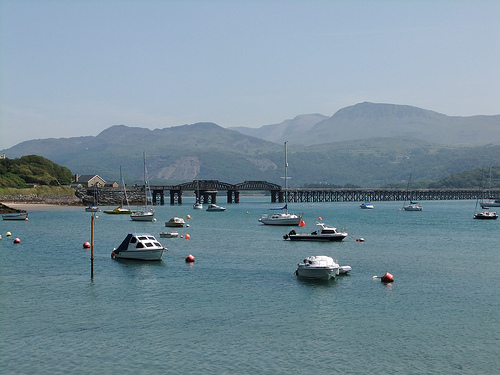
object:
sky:
[1, 1, 492, 150]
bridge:
[76, 180, 500, 204]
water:
[2, 193, 500, 373]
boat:
[113, 232, 165, 263]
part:
[72, 173, 122, 191]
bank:
[3, 181, 153, 209]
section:
[148, 180, 283, 207]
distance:
[1, 3, 499, 198]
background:
[1, 2, 496, 193]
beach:
[2, 200, 89, 208]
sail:
[279, 138, 294, 214]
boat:
[258, 209, 302, 227]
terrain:
[2, 153, 77, 200]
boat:
[160, 229, 183, 240]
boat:
[166, 216, 187, 227]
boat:
[127, 207, 159, 222]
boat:
[105, 205, 136, 216]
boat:
[82, 205, 102, 214]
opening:
[173, 187, 279, 207]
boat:
[297, 253, 344, 281]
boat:
[284, 223, 350, 244]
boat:
[359, 201, 377, 211]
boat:
[400, 200, 424, 212]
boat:
[473, 211, 499, 220]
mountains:
[1, 102, 499, 196]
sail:
[139, 145, 153, 213]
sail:
[116, 167, 131, 209]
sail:
[192, 174, 205, 205]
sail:
[488, 165, 495, 199]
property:
[68, 174, 123, 201]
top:
[225, 112, 331, 146]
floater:
[374, 271, 395, 286]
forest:
[1, 140, 498, 190]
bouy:
[182, 253, 198, 265]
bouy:
[80, 239, 93, 253]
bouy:
[13, 235, 23, 246]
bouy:
[296, 219, 308, 229]